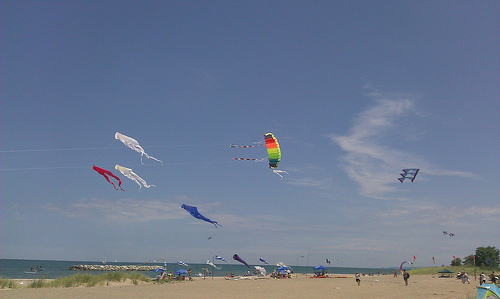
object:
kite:
[229, 133, 289, 179]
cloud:
[330, 80, 480, 158]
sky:
[0, 0, 498, 269]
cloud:
[70, 187, 275, 227]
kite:
[180, 204, 223, 230]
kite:
[93, 164, 122, 192]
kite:
[114, 132, 164, 168]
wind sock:
[232, 254, 253, 270]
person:
[355, 272, 362, 287]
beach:
[2, 272, 499, 299]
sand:
[49, 290, 136, 297]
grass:
[1, 267, 185, 290]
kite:
[398, 168, 419, 183]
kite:
[114, 164, 157, 191]